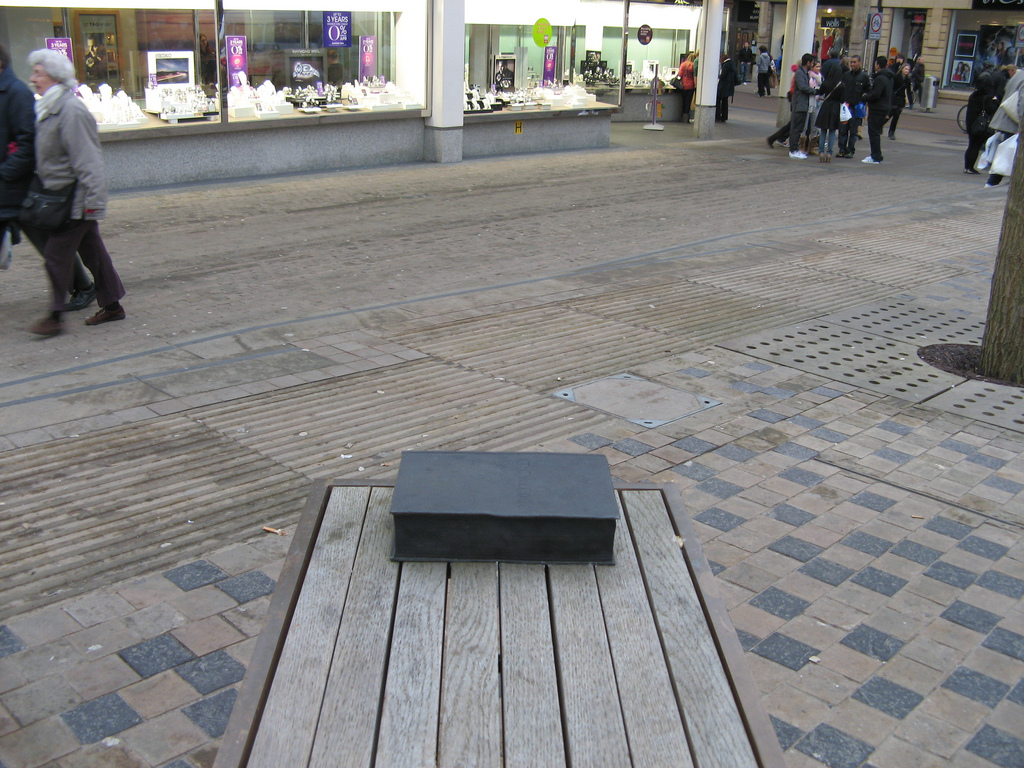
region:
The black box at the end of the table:
[380, 440, 630, 571]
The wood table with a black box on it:
[194, 462, 786, 766]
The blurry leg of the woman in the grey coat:
[26, 219, 78, 343]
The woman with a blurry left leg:
[14, 37, 138, 342]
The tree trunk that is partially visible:
[969, 132, 1021, 386]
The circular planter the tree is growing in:
[909, 332, 1023, 384]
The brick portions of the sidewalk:
[1, 268, 1022, 767]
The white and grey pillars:
[696, 0, 821, 134]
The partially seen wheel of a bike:
[952, 97, 971, 135]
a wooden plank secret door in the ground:
[242, 481, 762, 766]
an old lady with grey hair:
[26, 47, 125, 327]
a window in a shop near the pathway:
[65, 2, 430, 136]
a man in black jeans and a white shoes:
[860, 50, 895, 168]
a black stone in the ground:
[209, 566, 280, 601]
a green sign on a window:
[531, 19, 558, 43]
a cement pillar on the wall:
[419, 120, 468, 165]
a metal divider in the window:
[213, 0, 232, 128]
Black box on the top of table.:
[374, 432, 628, 592]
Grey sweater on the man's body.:
[8, 72, 151, 250]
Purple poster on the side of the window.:
[321, 16, 359, 51]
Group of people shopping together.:
[789, 54, 923, 173]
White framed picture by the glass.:
[157, 54, 218, 132]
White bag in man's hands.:
[827, 107, 870, 136]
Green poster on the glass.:
[520, 10, 558, 50]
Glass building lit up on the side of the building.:
[90, 22, 733, 156]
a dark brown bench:
[255, 375, 726, 742]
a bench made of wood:
[291, 476, 737, 767]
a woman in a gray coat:
[35, 97, 109, 195]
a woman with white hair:
[24, 41, 76, 87]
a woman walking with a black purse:
[24, 160, 83, 272]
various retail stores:
[111, 13, 839, 211]